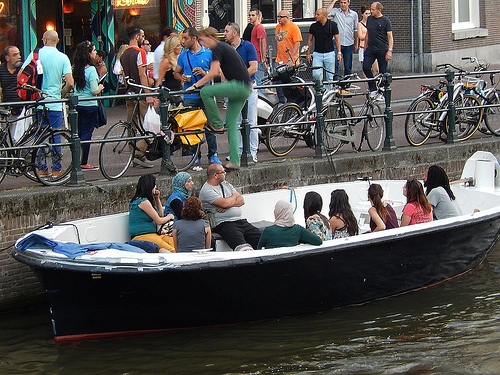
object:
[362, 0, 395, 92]
person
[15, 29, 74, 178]
person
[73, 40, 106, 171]
person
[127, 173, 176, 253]
person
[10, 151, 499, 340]
boat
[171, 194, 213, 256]
person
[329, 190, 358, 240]
girl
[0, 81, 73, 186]
bicycle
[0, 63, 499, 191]
walkway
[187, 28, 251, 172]
person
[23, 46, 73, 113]
shirt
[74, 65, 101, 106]
shirt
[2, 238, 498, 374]
water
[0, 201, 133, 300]
wall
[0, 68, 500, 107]
railing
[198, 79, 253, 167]
pants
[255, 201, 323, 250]
woman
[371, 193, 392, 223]
tail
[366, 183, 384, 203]
head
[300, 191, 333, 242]
girl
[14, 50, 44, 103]
backpack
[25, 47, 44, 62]
shoulder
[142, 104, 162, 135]
bag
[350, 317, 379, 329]
ripples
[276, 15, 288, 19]
glasses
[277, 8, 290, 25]
head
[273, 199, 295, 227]
head wrap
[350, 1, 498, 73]
building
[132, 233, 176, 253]
yellow pants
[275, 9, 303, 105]
man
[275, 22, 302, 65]
t-shirt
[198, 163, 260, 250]
man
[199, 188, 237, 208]
arms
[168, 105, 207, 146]
bag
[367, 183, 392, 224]
hairstyle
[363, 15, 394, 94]
black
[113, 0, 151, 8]
sign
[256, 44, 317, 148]
scooter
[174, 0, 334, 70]
building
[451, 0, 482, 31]
window